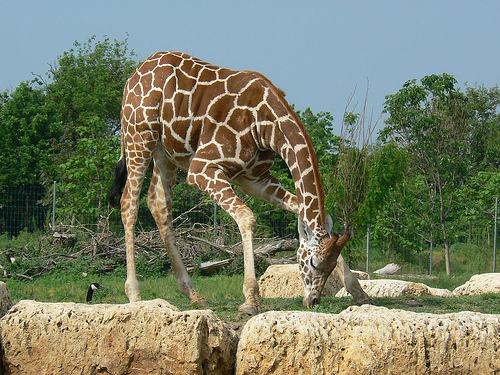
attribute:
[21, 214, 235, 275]
branches — on the ground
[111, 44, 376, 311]
giraffe — tall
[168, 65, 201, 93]
spot — brown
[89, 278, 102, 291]
face — white, black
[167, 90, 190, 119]
patches — brown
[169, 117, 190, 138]
patches — brown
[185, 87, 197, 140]
line — white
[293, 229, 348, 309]
head — down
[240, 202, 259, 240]
knee — bent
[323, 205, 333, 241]
knee — bent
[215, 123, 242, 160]
spot — brown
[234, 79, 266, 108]
spot — brown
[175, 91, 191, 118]
spot — brown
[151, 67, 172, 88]
spot — brown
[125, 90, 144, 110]
spot — brown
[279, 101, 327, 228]
neck — long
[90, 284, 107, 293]
face — black and white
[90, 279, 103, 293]
head — black and white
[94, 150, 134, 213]
giraffe — black tail 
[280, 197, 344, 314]
giraffe — head 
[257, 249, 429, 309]
rock — tan, large white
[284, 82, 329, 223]
giraffe — mane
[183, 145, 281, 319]
giraffe — leg 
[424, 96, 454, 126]
tree —  green leaves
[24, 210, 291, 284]
brush — sticks 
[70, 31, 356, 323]
giraffe — bending 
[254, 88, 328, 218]
giraffe — bent spotted neck 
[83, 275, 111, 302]
duck — neck , head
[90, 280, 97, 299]
duck — head, white spot 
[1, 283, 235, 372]
stone — large 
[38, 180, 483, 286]
fencing — metal 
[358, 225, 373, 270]
pole — gray metal fence